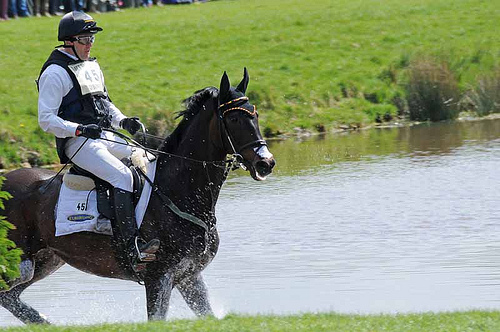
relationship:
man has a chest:
[31, 12, 151, 212] [65, 60, 107, 102]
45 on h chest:
[79, 67, 102, 87] [65, 60, 107, 102]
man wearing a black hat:
[33, 7, 168, 274] [261, 155, 322, 188]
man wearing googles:
[33, 7, 168, 274] [58, 28, 100, 49]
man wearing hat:
[33, 7, 168, 274] [53, 9, 108, 66]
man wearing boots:
[33, 7, 168, 274] [104, 180, 171, 300]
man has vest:
[33, 7, 168, 274] [33, 39, 130, 142]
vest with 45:
[33, 39, 130, 142] [81, 68, 106, 83]